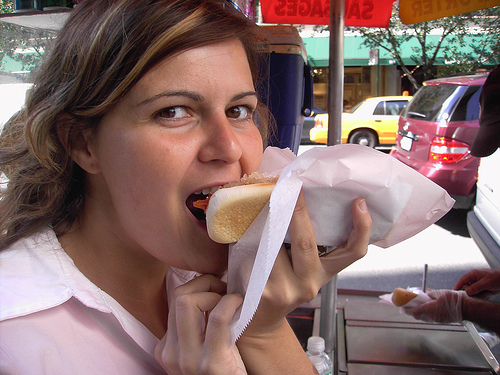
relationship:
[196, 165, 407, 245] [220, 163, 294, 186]
hotdog has onion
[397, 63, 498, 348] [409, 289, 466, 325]
worker has glove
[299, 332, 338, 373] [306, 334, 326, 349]
bottle has top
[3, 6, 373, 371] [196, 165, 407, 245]
woman eating hotdog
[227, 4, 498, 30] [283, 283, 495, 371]
umbrella covering cart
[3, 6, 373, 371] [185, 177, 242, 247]
woman has mouth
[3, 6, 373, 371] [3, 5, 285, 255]
woman has hair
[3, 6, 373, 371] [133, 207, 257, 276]
woman has jaw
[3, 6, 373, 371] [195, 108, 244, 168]
woman has nose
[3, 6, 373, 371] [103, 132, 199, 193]
woman has cheek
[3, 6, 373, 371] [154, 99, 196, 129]
woman has eye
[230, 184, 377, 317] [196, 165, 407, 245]
hand grasping hotdog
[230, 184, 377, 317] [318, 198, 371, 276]
hand has finger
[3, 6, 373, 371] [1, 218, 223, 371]
woman wearing shirt